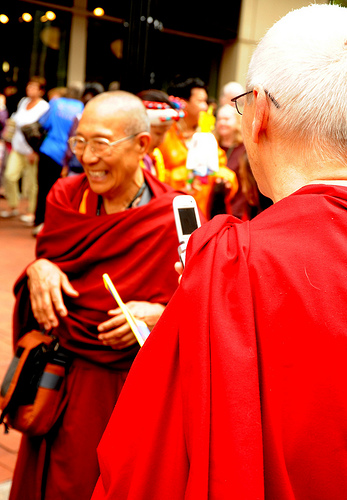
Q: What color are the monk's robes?
A: Red.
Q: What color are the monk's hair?
A: White.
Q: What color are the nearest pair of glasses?
A: Black.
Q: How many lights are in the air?
A: 5.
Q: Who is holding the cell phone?
A: Monk.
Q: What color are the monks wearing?
A: Red.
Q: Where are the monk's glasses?
A: On faces.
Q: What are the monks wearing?
A: Robes.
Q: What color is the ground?
A: Red.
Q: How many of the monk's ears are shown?
A: 2.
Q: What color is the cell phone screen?
A: Black.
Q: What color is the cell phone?
A: Greyw.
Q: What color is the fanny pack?
A: Orange.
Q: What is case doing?
A: Hanging.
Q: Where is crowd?
A: Behind costumes.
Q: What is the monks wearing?
A: Eye glasses and dress.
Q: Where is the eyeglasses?
A: On his eyes.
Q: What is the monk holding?
A: Mobile phone.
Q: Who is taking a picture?
A: The monk.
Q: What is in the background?
A: Crowd.